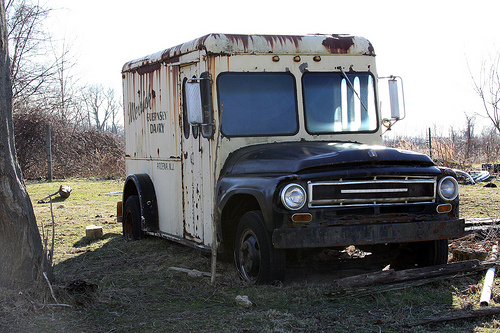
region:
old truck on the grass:
[106, 23, 480, 277]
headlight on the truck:
[281, 175, 313, 217]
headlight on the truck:
[436, 174, 460, 209]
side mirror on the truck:
[175, 75, 222, 150]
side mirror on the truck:
[386, 76, 415, 128]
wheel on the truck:
[228, 222, 268, 280]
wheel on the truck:
[117, 187, 149, 242]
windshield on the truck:
[218, 74, 297, 145]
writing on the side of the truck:
[125, 80, 175, 152]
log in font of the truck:
[335, 269, 489, 301]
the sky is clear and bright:
[52, 16, 474, 128]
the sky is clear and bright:
[373, 21, 490, 163]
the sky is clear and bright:
[257, 3, 462, 170]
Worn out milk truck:
[106, 22, 474, 292]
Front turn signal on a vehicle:
[280, 205, 325, 226]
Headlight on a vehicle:
[278, 170, 309, 216]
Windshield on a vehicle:
[206, 65, 381, 140]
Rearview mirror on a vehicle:
[375, 67, 411, 132]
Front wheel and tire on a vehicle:
[227, 210, 282, 292]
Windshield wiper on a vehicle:
[328, 60, 368, 120]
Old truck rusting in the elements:
[100, 22, 476, 293]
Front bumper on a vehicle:
[265, 212, 470, 252]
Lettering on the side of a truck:
[120, 86, 170, 146]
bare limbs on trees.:
[18, 4, 40, 51]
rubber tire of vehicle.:
[233, 222, 266, 268]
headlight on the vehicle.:
[281, 181, 306, 208]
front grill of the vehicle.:
[315, 180, 426, 213]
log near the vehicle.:
[339, 273, 485, 285]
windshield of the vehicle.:
[230, 86, 283, 128]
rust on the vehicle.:
[118, 65, 170, 87]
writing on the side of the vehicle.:
[142, 107, 166, 134]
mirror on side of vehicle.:
[391, 75, 408, 125]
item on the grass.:
[82, 220, 106, 245]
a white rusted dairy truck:
[115, 32, 463, 284]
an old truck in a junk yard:
[2, 32, 499, 330]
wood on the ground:
[335, 259, 499, 331]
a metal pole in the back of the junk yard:
[42, 122, 57, 179]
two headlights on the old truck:
[278, 175, 458, 210]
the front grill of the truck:
[308, 177, 437, 204]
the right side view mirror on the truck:
[183, 77, 206, 127]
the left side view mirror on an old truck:
[380, 74, 405, 125]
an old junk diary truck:
[115, 33, 465, 285]